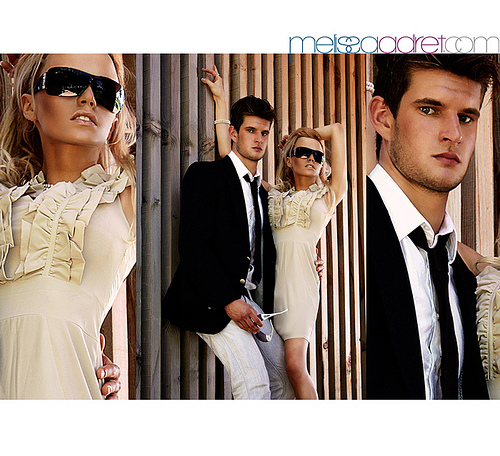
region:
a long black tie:
[408, 229, 462, 395]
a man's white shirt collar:
[362, 164, 461, 266]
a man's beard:
[388, 122, 467, 192]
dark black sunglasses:
[285, 145, 327, 164]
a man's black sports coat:
[160, 155, 280, 336]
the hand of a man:
[92, 333, 132, 400]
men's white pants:
[198, 297, 297, 397]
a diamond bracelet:
[208, 113, 233, 125]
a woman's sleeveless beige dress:
[260, 182, 332, 340]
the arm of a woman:
[318, 124, 353, 194]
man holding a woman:
[158, 60, 355, 408]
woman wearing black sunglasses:
[278, 131, 328, 182]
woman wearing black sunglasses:
[14, 55, 133, 165]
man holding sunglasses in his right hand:
[163, 94, 293, 402]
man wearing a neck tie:
[364, 58, 497, 445]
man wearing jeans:
[168, 87, 293, 408]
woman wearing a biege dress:
[197, 63, 348, 453]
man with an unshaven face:
[365, 52, 498, 195]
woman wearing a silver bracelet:
[199, 62, 354, 234]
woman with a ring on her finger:
[193, 61, 356, 213]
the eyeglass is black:
[273, 140, 354, 182]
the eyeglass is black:
[268, 120, 338, 190]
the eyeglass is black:
[286, 130, 340, 174]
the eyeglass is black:
[287, 137, 349, 212]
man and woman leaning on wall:
[232, 294, 297, 346]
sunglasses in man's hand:
[239, 292, 294, 341]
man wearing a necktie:
[381, 155, 488, 390]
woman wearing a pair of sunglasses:
[282, 125, 337, 185]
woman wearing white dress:
[270, 175, 332, 335]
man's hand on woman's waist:
[86, 327, 141, 398]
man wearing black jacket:
[190, 156, 266, 331]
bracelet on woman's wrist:
[207, 110, 232, 140]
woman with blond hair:
[286, 120, 346, 195]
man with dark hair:
[234, 88, 277, 158]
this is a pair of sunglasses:
[25, 67, 128, 108]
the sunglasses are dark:
[51, 71, 118, 102]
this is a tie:
[419, 232, 459, 398]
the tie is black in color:
[427, 247, 448, 279]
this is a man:
[367, 61, 498, 384]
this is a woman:
[2, 59, 143, 398]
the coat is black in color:
[196, 185, 239, 277]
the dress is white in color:
[289, 237, 308, 305]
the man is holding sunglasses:
[246, 307, 301, 355]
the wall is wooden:
[280, 64, 327, 93]